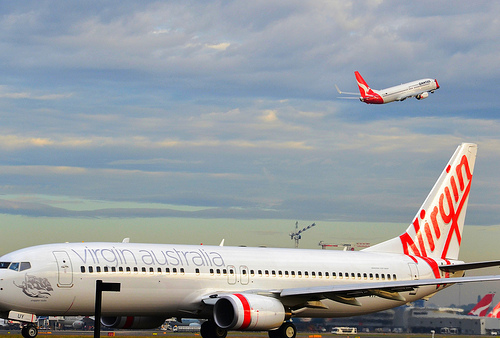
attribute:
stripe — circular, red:
[222, 287, 260, 328]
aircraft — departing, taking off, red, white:
[334, 60, 446, 115]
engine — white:
[212, 289, 287, 332]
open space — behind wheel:
[40, 318, 92, 337]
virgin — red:
[396, 151, 477, 283]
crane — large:
[317, 236, 371, 252]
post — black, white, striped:
[287, 219, 324, 241]